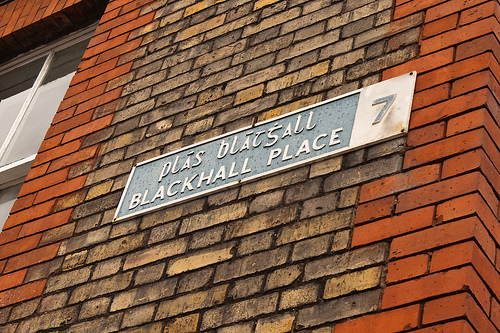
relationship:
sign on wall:
[111, 69, 415, 223] [2, 0, 498, 332]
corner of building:
[452, 5, 489, 329] [239, 26, 415, 63]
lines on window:
[5, 30, 76, 260] [4, 4, 108, 254]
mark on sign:
[385, 111, 408, 134] [86, 51, 441, 198]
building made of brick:
[0, 0, 484, 328] [275, 205, 355, 248]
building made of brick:
[0, 0, 484, 328] [82, 227, 151, 267]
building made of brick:
[0, 0, 484, 328] [347, 202, 435, 249]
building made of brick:
[0, 0, 484, 328] [107, 95, 157, 127]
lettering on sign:
[129, 110, 343, 210] [111, 69, 415, 223]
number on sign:
[371, 93, 397, 124] [111, 69, 415, 223]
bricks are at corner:
[273, 206, 361, 247] [440, 4, 493, 330]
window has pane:
[0, 0, 109, 226] [12, 37, 106, 183]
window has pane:
[0, 0, 109, 226] [3, 50, 51, 165]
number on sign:
[357, 89, 398, 128] [111, 69, 415, 223]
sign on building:
[111, 69, 415, 223] [0, 0, 484, 328]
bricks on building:
[349, 176, 499, 281] [0, 0, 484, 328]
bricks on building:
[269, 212, 456, 332] [0, 0, 484, 328]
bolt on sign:
[410, 72, 413, 75] [111, 69, 415, 223]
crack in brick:
[288, 272, 303, 282] [260, 262, 304, 290]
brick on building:
[260, 262, 304, 290] [0, 0, 484, 328]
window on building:
[0, 3, 104, 244] [0, 0, 484, 328]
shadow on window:
[0, 57, 89, 91] [0, 3, 104, 244]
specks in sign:
[327, 100, 352, 122] [111, 69, 415, 223]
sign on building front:
[111, 69, 415, 223] [3, 2, 495, 331]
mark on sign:
[382, 105, 408, 133] [99, 77, 424, 236]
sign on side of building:
[111, 69, 415, 223] [0, 0, 484, 328]